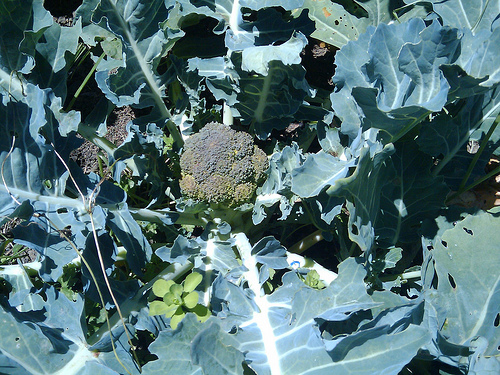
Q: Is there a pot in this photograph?
A: No, there are no pots.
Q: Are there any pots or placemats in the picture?
A: No, there are no pots or placemats.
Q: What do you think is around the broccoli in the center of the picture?
A: The leaves are around the broccoli.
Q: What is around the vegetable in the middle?
A: The leaves are around the broccoli.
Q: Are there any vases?
A: No, there are no vases.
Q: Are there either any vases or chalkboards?
A: No, there are no vases or chalkboards.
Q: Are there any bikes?
A: No, there are no bikes.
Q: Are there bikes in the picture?
A: No, there are no bikes.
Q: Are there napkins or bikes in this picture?
A: No, there are no bikes or napkins.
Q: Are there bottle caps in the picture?
A: No, there are no bottle caps.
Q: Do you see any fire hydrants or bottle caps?
A: No, there are no bottle caps or fire hydrants.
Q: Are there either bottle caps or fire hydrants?
A: No, there are no bottle caps or fire hydrants.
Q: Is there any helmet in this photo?
A: No, there are no helmets.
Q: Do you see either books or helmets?
A: No, there are no helmets or books.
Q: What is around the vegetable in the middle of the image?
A: The leaves are around the broccoli.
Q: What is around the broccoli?
A: The leaves are around the broccoli.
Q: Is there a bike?
A: No, there are no bikes.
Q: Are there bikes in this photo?
A: No, there are no bikes.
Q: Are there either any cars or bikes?
A: No, there are no bikes or cars.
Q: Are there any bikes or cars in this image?
A: No, there are no bikes or cars.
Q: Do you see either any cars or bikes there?
A: No, there are no bikes or cars.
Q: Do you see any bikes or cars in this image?
A: No, there are no bikes or cars.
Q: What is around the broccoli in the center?
A: The leaves are around the broccoli.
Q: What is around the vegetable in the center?
A: The leaves are around the broccoli.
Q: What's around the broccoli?
A: The leaves are around the broccoli.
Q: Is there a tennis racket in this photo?
A: No, there are no rackets.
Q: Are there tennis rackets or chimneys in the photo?
A: No, there are no tennis rackets or chimneys.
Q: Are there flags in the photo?
A: No, there are no flags.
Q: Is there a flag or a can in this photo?
A: No, there are no flags or cans.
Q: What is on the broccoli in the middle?
A: The leaves are on the broccoli.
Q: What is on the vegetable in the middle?
A: The leaves are on the broccoli.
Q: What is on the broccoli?
A: The leaves are on the broccoli.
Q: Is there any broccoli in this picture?
A: Yes, there is broccoli.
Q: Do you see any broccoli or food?
A: Yes, there is broccoli.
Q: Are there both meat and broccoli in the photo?
A: No, there is broccoli but no meat.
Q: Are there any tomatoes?
A: No, there are no tomatoes.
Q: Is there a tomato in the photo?
A: No, there are no tomatoes.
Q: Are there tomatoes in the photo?
A: No, there are no tomatoes.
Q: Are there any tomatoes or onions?
A: No, there are no tomatoes or onions.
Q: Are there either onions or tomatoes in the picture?
A: No, there are no tomatoes or onions.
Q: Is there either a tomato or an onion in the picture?
A: No, there are no tomatoes or onions.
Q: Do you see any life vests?
A: No, there are no life vests.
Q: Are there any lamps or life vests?
A: No, there are no life vests or lamps.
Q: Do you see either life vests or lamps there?
A: No, there are no life vests or lamps.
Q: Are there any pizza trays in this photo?
A: No, there are no pizza trays.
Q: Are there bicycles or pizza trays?
A: No, there are no pizza trays or bicycles.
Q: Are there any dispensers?
A: No, there are no dispensers.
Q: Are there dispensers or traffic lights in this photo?
A: No, there are no dispensers or traffic lights.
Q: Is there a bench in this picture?
A: No, there are no benches.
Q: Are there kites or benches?
A: No, there are no benches or kites.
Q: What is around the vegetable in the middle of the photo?
A: The leaves are around the broccoli.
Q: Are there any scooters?
A: No, there are no scooters.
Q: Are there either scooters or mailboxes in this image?
A: No, there are no scooters or mailboxes.